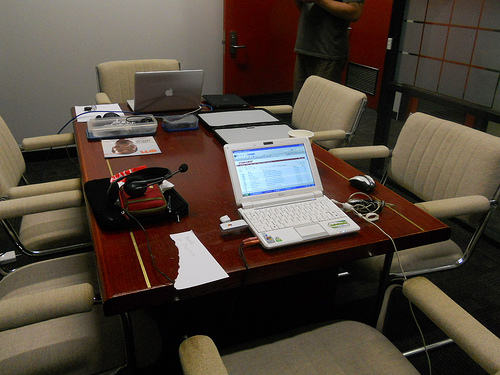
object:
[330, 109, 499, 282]
chair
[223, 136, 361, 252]
laptop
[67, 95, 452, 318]
table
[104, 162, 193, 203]
headphone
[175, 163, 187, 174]
mic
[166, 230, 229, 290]
paper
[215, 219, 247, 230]
usb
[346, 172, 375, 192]
mouse